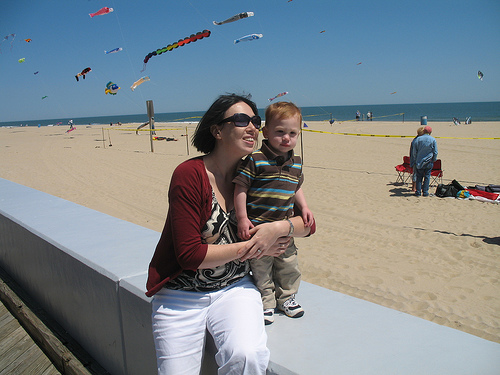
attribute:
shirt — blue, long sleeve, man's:
[414, 134, 438, 169]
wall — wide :
[22, 187, 163, 347]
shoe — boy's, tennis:
[262, 305, 272, 322]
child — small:
[245, 89, 318, 322]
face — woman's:
[221, 102, 266, 157]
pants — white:
[145, 281, 272, 373]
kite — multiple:
[232, 30, 266, 45]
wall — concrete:
[10, 166, 132, 336]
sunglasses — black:
[213, 112, 262, 128]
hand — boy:
[298, 209, 312, 229]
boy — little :
[235, 99, 313, 325]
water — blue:
[4, 103, 498, 130]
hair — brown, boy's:
[246, 87, 323, 135]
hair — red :
[262, 102, 303, 128]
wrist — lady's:
[282, 220, 290, 232]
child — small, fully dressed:
[232, 101, 314, 323]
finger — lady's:
[243, 241, 258, 263]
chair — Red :
[398, 156, 415, 184]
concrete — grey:
[331, 326, 402, 356]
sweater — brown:
[169, 176, 197, 260]